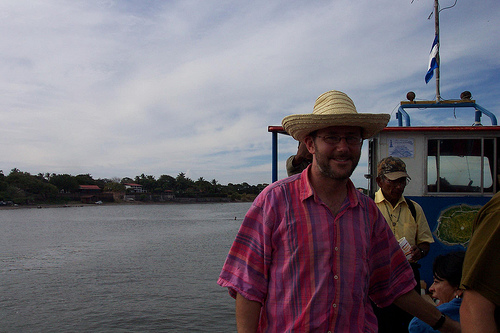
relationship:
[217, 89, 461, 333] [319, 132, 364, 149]
man has glasses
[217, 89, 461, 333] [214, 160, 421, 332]
man wears shirt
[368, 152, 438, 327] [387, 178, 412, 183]
man has glasses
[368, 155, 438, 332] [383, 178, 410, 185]
man wears glasses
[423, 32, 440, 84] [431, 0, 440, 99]
flag on pole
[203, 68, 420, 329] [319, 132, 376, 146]
man wears glasses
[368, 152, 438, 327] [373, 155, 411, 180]
man wears cap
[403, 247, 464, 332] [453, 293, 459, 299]
woman wears earring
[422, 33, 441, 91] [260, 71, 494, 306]
flag on boat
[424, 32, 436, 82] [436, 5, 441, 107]
flag on pole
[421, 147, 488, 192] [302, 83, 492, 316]
window on boat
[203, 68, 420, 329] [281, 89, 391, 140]
man wearing officerhat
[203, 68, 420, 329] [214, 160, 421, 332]
man wearing shirt